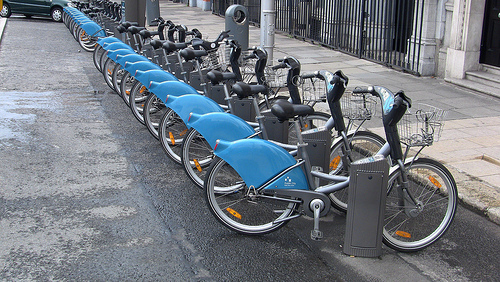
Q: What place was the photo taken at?
A: It was taken at the sidewalk.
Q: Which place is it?
A: It is a sidewalk.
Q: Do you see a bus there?
A: No, there are no buses.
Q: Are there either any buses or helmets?
A: No, there are no buses or helmets.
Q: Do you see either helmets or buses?
A: No, there are no buses or helmets.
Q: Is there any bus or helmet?
A: No, there are no buses or helmets.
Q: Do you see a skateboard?
A: No, there are no skateboards.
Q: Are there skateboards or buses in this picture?
A: No, there are no skateboards or buses.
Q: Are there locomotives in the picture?
A: No, there are no locomotives.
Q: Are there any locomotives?
A: No, there are no locomotives.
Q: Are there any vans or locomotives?
A: No, there are no locomotives or vans.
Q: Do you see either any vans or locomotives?
A: No, there are no locomotives or vans.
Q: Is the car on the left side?
A: Yes, the car is on the left of the image.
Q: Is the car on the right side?
A: No, the car is on the left of the image.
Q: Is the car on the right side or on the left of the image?
A: The car is on the left of the image.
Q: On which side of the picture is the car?
A: The car is on the left of the image.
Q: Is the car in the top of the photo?
A: Yes, the car is in the top of the image.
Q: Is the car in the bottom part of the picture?
A: No, the car is in the top of the image.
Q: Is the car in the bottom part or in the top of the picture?
A: The car is in the top of the image.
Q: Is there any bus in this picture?
A: No, there are no buses.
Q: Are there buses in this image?
A: No, there are no buses.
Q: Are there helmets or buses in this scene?
A: No, there are no buses or helmets.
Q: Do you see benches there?
A: No, there are no benches.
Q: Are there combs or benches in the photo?
A: No, there are no benches or combs.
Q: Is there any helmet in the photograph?
A: No, there are no helmets.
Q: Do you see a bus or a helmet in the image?
A: No, there are no helmets or buses.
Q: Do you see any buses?
A: No, there are no buses.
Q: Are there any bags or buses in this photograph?
A: No, there are no buses or bags.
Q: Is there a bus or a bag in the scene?
A: No, there are no buses or bags.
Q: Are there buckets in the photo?
A: No, there are no buckets.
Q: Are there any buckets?
A: No, there are no buckets.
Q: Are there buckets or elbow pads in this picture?
A: No, there are no buckets or elbow pads.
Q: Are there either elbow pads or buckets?
A: No, there are no buckets or elbow pads.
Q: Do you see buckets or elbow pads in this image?
A: No, there are no buckets or elbow pads.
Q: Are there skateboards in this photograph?
A: No, there are no skateboards.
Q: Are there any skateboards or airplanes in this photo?
A: No, there are no skateboards or airplanes.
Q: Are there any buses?
A: No, there are no buses.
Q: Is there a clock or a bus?
A: No, there are no buses or clocks.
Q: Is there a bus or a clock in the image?
A: No, there are no buses or clocks.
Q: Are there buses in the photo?
A: No, there are no buses.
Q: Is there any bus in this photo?
A: No, there are no buses.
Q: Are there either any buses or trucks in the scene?
A: No, there are no buses or trucks.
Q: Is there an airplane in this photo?
A: No, there are no airplanes.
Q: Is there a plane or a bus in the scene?
A: No, there are no airplanes or buses.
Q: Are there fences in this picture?
A: Yes, there is a fence.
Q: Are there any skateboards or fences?
A: Yes, there is a fence.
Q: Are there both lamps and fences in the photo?
A: No, there is a fence but no lamps.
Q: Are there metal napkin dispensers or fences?
A: Yes, there is a metal fence.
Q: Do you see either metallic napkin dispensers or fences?
A: Yes, there is a metal fence.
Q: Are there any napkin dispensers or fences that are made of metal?
A: Yes, the fence is made of metal.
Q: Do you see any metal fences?
A: Yes, there is a metal fence.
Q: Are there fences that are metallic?
A: Yes, there is a fence that is metallic.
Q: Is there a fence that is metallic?
A: Yes, there is a fence that is metallic.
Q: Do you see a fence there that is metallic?
A: Yes, there is a fence that is metallic.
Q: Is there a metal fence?
A: Yes, there is a fence that is made of metal.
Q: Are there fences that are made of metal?
A: Yes, there is a fence that is made of metal.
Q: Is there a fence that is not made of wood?
A: Yes, there is a fence that is made of metal.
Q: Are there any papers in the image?
A: No, there are no papers.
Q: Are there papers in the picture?
A: No, there are no papers.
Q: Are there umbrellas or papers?
A: No, there are no papers or umbrellas.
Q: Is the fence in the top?
A: Yes, the fence is in the top of the image.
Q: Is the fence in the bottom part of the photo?
A: No, the fence is in the top of the image.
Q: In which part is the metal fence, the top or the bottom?
A: The fence is in the top of the image.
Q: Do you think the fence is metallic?
A: Yes, the fence is metallic.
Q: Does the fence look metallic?
A: Yes, the fence is metallic.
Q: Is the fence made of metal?
A: Yes, the fence is made of metal.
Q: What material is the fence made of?
A: The fence is made of metal.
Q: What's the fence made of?
A: The fence is made of metal.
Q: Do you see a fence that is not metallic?
A: No, there is a fence but it is metallic.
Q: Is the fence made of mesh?
A: No, the fence is made of metal.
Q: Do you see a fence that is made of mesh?
A: No, there is a fence but it is made of metal.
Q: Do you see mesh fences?
A: No, there is a fence but it is made of metal.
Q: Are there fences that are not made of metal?
A: No, there is a fence but it is made of metal.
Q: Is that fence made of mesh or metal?
A: The fence is made of metal.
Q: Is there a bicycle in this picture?
A: Yes, there are bicycles.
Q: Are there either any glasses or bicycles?
A: Yes, there are bicycles.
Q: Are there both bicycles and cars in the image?
A: Yes, there are both bicycles and a car.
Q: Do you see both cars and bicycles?
A: Yes, there are both bicycles and a car.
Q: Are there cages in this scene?
A: No, there are no cages.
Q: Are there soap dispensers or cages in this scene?
A: No, there are no cages or soap dispensers.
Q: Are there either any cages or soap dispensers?
A: No, there are no cages or soap dispensers.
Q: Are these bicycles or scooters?
A: These are bicycles.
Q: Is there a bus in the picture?
A: No, there are no buses.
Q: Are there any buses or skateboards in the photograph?
A: No, there are no buses or skateboards.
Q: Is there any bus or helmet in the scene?
A: No, there are no buses or helmets.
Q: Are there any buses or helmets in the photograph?
A: No, there are no buses or helmets.